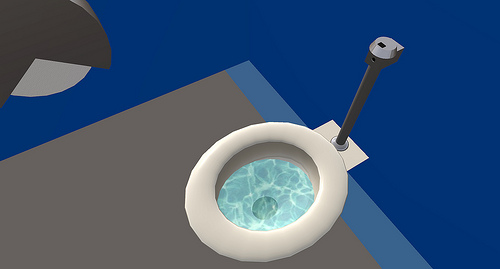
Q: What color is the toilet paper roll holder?
A: Black.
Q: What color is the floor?
A: Gray.